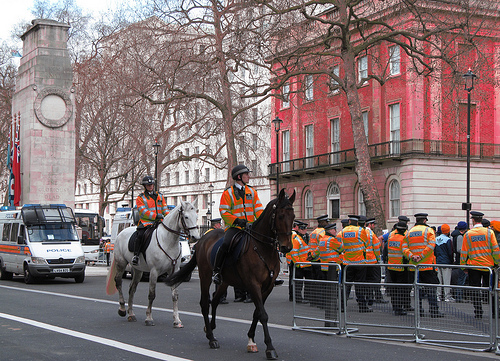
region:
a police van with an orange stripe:
[0, 196, 87, 288]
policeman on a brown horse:
[187, 136, 303, 355]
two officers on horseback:
[87, 145, 322, 360]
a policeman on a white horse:
[90, 160, 207, 332]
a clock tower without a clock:
[16, 14, 78, 206]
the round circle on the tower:
[27, 80, 77, 133]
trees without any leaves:
[94, 9, 394, 262]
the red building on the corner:
[270, 11, 498, 287]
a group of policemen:
[293, 209, 441, 314]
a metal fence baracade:
[290, 256, 492, 352]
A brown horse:
[167, 186, 301, 359]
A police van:
[0, 202, 84, 283]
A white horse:
[108, 197, 199, 328]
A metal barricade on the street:
[291, 260, 497, 351]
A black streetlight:
[151, 139, 163, 175]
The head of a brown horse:
[269, 184, 295, 256]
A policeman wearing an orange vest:
[459, 210, 497, 320]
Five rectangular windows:
[277, 100, 402, 171]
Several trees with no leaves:
[76, 0, 273, 162]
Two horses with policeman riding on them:
[104, 165, 299, 358]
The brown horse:
[165, 187, 304, 359]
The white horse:
[101, 193, 198, 330]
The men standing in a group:
[280, 207, 499, 319]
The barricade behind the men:
[285, 258, 499, 355]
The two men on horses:
[102, 162, 300, 357]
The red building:
[264, 78, 499, 230]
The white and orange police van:
[0, 203, 88, 282]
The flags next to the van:
[2, 112, 24, 213]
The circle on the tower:
[33, 83, 71, 127]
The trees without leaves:
[0, 1, 496, 233]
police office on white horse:
[101, 172, 193, 317]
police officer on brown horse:
[187, 164, 302, 351]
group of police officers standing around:
[286, 214, 498, 293]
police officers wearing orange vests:
[293, 215, 498, 267]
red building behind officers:
[272, 1, 498, 162]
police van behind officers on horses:
[3, 199, 88, 282]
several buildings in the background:
[6, 27, 491, 216]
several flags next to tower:
[3, 112, 26, 208]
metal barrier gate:
[285, 254, 497, 348]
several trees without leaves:
[10, 6, 484, 209]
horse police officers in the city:
[91, 156, 327, 356]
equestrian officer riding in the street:
[193, 151, 299, 347]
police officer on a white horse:
[90, 177, 196, 319]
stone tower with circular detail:
[16, 11, 87, 205]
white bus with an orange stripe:
[5, 201, 88, 287]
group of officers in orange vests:
[296, 204, 496, 253]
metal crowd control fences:
[287, 256, 493, 336]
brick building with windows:
[259, 11, 484, 217]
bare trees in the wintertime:
[84, 31, 273, 170]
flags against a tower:
[1, 114, 29, 204]